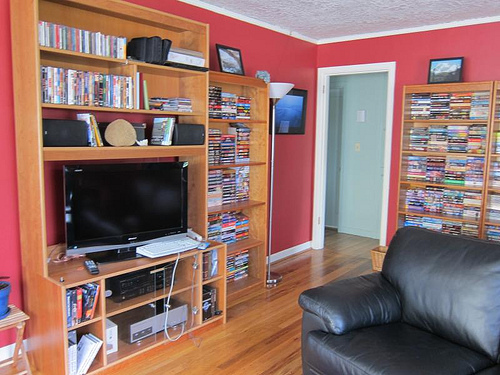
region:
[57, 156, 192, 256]
Television on a entertainment center.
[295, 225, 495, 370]
A black leather sofa.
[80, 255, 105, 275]
Remote control on entertainment center.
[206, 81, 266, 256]
Books on entertainment center.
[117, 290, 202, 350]
DVR on entertainment center.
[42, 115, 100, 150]
A speaker on entertainment center.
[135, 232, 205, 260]
Keyboard on entertainment center.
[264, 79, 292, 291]
Lamp standing next to entertainment center.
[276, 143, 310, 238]
Pink wall of room.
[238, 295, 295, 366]
Wood floor of room.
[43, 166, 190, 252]
flat screen tv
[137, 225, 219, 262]
white keyboard on tv mantel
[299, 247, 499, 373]
black leather couch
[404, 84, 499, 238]
book shelf with books stacked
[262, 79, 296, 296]
white and silver floor lamp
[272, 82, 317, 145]
blue portrait on wall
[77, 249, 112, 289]
tv remote on tv mantel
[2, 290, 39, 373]
wooden folding table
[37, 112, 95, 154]
black speaker on shelf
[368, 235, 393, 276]
wooven trash can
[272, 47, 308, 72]
portion of dark pink wall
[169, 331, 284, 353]
portion of shiny oak floor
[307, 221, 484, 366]
shiny leather sofa with rest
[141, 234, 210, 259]
white computer keyboard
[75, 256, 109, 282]
black remote with white buttons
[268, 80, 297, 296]
white lamp with silver base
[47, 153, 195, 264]
black television with base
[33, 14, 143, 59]
stack of book on shelf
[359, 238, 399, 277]
small wicker basket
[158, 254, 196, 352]
cord from computer keyboard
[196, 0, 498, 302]
three brown wooden bookshelves full of video games.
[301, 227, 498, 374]
A black leather sofa in front of a tv.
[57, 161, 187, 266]
A black tv on an entertainment center.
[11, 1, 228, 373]
An entertainment center against a red wall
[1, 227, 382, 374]
brown hard wood flooring in a room.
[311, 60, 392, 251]
A white trimmed doorway.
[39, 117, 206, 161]
A shelf in the entertainment center with two speakers on it.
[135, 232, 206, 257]
a white keyboard under a tv.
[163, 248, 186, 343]
a white cord dangling down from a keyboard.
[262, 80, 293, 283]
A tall lamp by a brown book case.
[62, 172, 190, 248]
the television in the entertainment system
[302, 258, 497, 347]
the black couch in the room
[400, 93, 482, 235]
a book shelf filled with movie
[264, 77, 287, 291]
a tall lamp on the floor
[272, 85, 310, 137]
a blue photo on the wall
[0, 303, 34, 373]
a wooden stand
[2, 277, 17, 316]
a blue pot on the stand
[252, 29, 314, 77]
the red wall of the room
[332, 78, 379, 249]
the blue wall in the hallway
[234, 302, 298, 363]
the wooden floor in the room